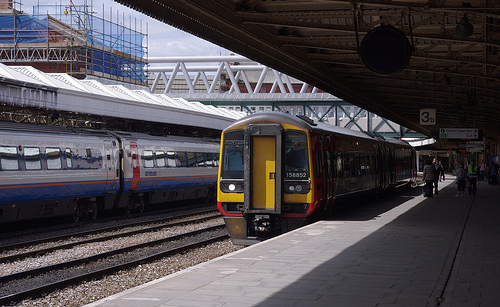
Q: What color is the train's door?
A: Yellow.